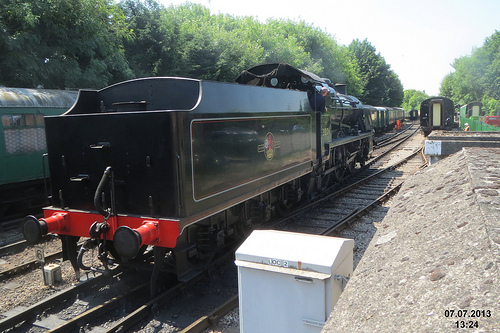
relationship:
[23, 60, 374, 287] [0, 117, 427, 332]
train on track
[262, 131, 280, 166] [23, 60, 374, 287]
logo on train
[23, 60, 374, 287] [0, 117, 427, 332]
train over track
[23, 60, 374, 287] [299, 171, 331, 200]
train has wheel